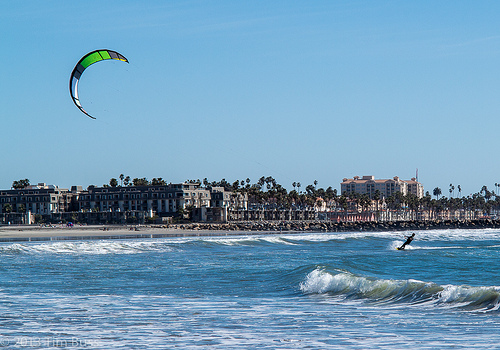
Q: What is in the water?
A: Foam.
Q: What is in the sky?
A: Sail.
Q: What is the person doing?
A: Parasailing.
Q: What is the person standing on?
A: Board.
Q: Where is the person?
A: In the water.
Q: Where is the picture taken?
A: At the beach.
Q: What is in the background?
A: Buildings.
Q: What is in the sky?
A: Parachute.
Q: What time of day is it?
A: Afternoon.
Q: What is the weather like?
A: Sunny.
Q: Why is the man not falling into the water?
A: Held up by the kite.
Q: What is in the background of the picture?
A: A city.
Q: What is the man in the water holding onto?
A: A kite.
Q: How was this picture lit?
A: Sunlight.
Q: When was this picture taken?
A: Daytime.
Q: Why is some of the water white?
A: Waves.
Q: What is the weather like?
A: Clear and sunny.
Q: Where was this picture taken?
A: On a beach.